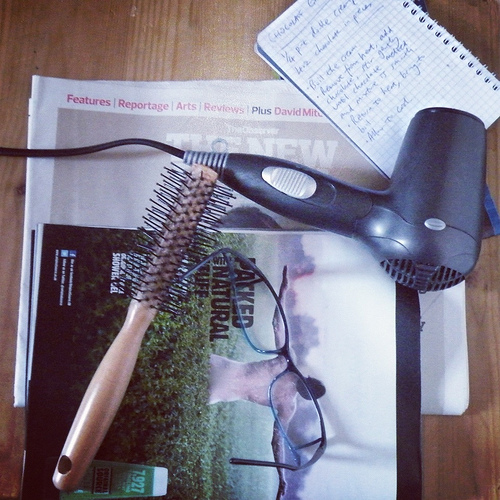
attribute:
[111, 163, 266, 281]
hairbrush —  brown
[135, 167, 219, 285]
brissles — black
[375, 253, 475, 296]
vent — black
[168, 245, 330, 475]
glasses — black, Blue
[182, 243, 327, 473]
glasses — pair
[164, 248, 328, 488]
eyeglasses — black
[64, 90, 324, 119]
writings — red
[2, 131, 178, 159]
cord — black,  electric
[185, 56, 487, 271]
dryer — black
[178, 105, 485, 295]
blowdryer — black, grey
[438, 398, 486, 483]
woodgrain — brown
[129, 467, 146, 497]
numbers — green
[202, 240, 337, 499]
glasses — blue, prescription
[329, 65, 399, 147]
written — blue ink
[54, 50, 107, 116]
table top —  wooden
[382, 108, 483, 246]
top — black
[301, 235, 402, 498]
part — white